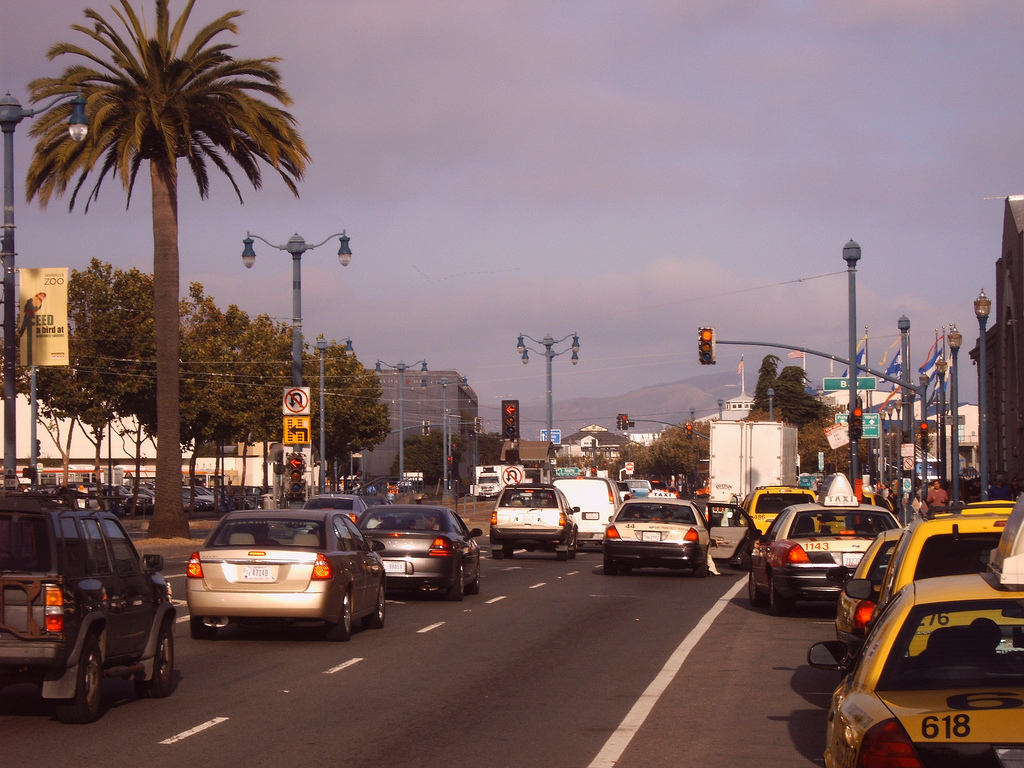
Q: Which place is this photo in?
A: It is at the road.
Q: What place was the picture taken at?
A: It was taken at the road.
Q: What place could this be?
A: It is a road.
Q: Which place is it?
A: It is a road.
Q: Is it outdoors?
A: Yes, it is outdoors.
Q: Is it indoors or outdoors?
A: It is outdoors.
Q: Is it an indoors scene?
A: No, it is outdoors.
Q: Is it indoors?
A: No, it is outdoors.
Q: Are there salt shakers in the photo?
A: No, there are no salt shakers.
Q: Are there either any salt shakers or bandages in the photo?
A: No, there are no salt shakers or bandages.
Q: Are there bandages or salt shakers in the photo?
A: No, there are no salt shakers or bandages.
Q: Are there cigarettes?
A: No, there are no cigarettes.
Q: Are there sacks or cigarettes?
A: No, there are no cigarettes or sacks.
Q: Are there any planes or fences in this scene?
A: No, there are no fences or planes.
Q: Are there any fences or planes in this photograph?
A: No, there are no fences or planes.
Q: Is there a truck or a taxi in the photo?
A: Yes, there is a taxi.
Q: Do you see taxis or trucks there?
A: Yes, there is a taxi.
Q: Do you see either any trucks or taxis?
A: Yes, there is a taxi.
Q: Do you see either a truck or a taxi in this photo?
A: Yes, there is a taxi.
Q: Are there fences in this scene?
A: No, there are no fences.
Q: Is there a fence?
A: No, there are no fences.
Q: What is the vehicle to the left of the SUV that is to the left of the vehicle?
A: The vehicle is a car.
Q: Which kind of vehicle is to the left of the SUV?
A: The vehicle is a car.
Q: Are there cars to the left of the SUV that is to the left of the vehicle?
A: Yes, there is a car to the left of the SUV.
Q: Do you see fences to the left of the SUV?
A: No, there is a car to the left of the SUV.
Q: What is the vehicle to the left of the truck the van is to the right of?
A: The vehicle is a car.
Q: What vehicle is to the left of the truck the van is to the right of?
A: The vehicle is a car.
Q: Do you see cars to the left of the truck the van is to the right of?
A: Yes, there is a car to the left of the truck.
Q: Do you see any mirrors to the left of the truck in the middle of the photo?
A: No, there is a car to the left of the truck.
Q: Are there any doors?
A: Yes, there is a door.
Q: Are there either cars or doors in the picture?
A: Yes, there is a door.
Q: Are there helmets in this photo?
A: No, there are no helmets.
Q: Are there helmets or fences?
A: No, there are no helmets or fences.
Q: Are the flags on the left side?
A: No, the flags are on the right of the image.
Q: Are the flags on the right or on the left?
A: The flags are on the right of the image.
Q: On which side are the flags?
A: The flags are on the right of the image.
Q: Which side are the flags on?
A: The flags are on the right of the image.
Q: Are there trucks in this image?
A: Yes, there is a truck.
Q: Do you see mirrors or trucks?
A: Yes, there is a truck.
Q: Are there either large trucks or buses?
A: Yes, there is a large truck.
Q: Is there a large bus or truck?
A: Yes, there is a large truck.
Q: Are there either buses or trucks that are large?
A: Yes, the truck is large.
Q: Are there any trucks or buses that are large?
A: Yes, the truck is large.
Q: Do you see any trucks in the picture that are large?
A: Yes, there is a large truck.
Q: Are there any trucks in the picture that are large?
A: Yes, there is a truck that is large.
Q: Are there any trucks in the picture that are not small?
A: Yes, there is a large truck.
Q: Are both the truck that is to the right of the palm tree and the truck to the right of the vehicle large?
A: Yes, both the truck and the truck are large.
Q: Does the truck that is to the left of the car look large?
A: Yes, the truck is large.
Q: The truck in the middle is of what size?
A: The truck is large.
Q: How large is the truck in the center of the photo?
A: The truck is large.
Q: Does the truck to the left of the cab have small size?
A: No, the truck is large.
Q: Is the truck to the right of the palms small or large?
A: The truck is large.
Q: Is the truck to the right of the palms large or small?
A: The truck is large.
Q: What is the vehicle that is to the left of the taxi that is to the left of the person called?
A: The vehicle is a truck.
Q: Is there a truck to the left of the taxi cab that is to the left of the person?
A: Yes, there is a truck to the left of the taxi.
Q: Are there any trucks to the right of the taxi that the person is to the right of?
A: No, the truck is to the left of the taxi.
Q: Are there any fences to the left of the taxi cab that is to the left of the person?
A: No, there is a truck to the left of the taxi.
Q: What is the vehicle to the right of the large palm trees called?
A: The vehicle is a truck.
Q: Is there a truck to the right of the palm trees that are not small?
A: Yes, there is a truck to the right of the palms.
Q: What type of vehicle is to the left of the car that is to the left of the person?
A: The vehicle is a truck.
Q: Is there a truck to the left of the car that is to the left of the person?
A: Yes, there is a truck to the left of the car.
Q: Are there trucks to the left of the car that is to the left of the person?
A: Yes, there is a truck to the left of the car.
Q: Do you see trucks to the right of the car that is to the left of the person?
A: No, the truck is to the left of the car.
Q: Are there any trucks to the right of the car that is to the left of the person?
A: No, the truck is to the left of the car.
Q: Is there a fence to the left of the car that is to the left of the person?
A: No, there is a truck to the left of the car.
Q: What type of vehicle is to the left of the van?
A: The vehicle is a truck.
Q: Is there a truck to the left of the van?
A: Yes, there is a truck to the left of the van.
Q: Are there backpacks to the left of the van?
A: No, there is a truck to the left of the van.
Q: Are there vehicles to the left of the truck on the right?
A: Yes, there are vehicles to the left of the truck.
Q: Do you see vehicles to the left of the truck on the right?
A: Yes, there are vehicles to the left of the truck.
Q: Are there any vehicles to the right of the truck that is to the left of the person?
A: No, the vehicles are to the left of the truck.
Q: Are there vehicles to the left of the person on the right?
A: Yes, there are vehicles to the left of the person.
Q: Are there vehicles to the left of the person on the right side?
A: Yes, there are vehicles to the left of the person.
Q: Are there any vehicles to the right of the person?
A: No, the vehicles are to the left of the person.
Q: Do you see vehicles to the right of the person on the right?
A: No, the vehicles are to the left of the person.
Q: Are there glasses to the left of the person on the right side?
A: No, there are vehicles to the left of the person.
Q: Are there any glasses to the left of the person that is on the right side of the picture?
A: No, there are vehicles to the left of the person.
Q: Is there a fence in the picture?
A: No, there are no fences.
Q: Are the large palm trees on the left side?
A: Yes, the palm trees are on the left of the image.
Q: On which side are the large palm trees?
A: The palm trees are on the left of the image.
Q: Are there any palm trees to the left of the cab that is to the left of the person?
A: Yes, there are palm trees to the left of the cab.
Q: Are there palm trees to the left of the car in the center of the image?
A: Yes, there are palm trees to the left of the car.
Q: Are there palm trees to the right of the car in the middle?
A: No, the palm trees are to the left of the car.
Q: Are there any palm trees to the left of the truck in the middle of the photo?
A: Yes, there are palm trees to the left of the truck.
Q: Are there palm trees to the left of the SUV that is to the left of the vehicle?
A: Yes, there are palm trees to the left of the SUV.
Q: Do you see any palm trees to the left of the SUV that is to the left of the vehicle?
A: Yes, there are palm trees to the left of the SUV.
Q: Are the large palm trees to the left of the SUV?
A: Yes, the palms are to the left of the SUV.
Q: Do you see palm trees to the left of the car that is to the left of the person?
A: Yes, there are palm trees to the left of the car.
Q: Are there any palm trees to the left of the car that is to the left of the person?
A: Yes, there are palm trees to the left of the car.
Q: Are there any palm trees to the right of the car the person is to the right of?
A: No, the palm trees are to the left of the car.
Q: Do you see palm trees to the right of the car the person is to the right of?
A: No, the palm trees are to the left of the car.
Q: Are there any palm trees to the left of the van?
A: Yes, there are palm trees to the left of the van.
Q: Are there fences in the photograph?
A: No, there are no fences.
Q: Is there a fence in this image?
A: No, there are no fences.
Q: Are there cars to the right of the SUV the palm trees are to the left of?
A: Yes, there is a car to the right of the SUV.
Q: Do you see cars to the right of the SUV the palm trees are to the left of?
A: Yes, there is a car to the right of the SUV.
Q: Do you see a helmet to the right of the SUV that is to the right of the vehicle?
A: No, there is a car to the right of the SUV.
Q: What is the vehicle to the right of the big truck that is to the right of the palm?
A: The vehicle is a car.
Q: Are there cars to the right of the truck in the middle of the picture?
A: Yes, there is a car to the right of the truck.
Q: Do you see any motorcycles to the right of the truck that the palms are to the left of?
A: No, there is a car to the right of the truck.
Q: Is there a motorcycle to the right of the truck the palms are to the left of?
A: No, there is a car to the right of the truck.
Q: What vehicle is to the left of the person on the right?
A: The vehicle is a car.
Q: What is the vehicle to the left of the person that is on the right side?
A: The vehicle is a car.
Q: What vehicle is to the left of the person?
A: The vehicle is a car.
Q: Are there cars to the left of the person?
A: Yes, there is a car to the left of the person.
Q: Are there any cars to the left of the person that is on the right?
A: Yes, there is a car to the left of the person.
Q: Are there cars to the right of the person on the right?
A: No, the car is to the left of the person.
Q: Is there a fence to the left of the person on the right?
A: No, there is a car to the left of the person.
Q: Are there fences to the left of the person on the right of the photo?
A: No, there is a car to the left of the person.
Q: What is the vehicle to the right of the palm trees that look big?
A: The vehicle is a car.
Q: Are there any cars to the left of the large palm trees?
A: No, the car is to the right of the palm trees.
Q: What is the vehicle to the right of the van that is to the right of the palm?
A: The vehicle is a car.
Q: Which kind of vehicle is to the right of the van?
A: The vehicle is a car.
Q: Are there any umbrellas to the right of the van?
A: No, there is a car to the right of the van.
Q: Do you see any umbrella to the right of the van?
A: No, there is a car to the right of the van.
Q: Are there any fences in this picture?
A: No, there are no fences.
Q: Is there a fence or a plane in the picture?
A: No, there are no fences or airplanes.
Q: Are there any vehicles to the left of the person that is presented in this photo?
A: Yes, there is a vehicle to the left of the person.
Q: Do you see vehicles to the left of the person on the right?
A: Yes, there is a vehicle to the left of the person.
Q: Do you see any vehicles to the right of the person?
A: No, the vehicle is to the left of the person.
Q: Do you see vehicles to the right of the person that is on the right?
A: No, the vehicle is to the left of the person.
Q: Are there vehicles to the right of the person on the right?
A: No, the vehicle is to the left of the person.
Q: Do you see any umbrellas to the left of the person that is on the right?
A: No, there is a vehicle to the left of the person.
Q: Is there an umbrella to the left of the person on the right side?
A: No, there is a vehicle to the left of the person.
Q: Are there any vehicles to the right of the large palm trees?
A: Yes, there is a vehicle to the right of the palms.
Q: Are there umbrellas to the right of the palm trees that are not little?
A: No, there is a vehicle to the right of the palms.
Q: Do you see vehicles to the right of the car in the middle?
A: Yes, there is a vehicle to the right of the car.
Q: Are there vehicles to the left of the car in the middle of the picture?
A: No, the vehicle is to the right of the car.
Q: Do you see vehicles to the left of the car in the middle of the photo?
A: No, the vehicle is to the right of the car.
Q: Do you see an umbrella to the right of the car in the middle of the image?
A: No, there is a vehicle to the right of the car.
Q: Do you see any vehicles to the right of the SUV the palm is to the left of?
A: Yes, there is a vehicle to the right of the SUV.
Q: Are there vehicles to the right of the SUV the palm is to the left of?
A: Yes, there is a vehicle to the right of the SUV.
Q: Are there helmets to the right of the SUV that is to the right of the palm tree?
A: No, there is a vehicle to the right of the SUV.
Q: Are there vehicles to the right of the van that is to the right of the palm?
A: Yes, there is a vehicle to the right of the van.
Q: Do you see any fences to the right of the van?
A: No, there is a vehicle to the right of the van.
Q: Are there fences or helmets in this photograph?
A: No, there are no fences or helmets.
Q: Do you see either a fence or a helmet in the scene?
A: No, there are no fences or helmets.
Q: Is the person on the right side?
A: Yes, the person is on the right of the image.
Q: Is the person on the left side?
A: No, the person is on the right of the image.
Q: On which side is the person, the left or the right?
A: The person is on the right of the image.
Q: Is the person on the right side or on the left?
A: The person is on the right of the image.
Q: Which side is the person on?
A: The person is on the right of the image.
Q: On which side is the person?
A: The person is on the right of the image.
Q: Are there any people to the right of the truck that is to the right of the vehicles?
A: Yes, there is a person to the right of the truck.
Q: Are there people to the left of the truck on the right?
A: No, the person is to the right of the truck.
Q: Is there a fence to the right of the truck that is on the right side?
A: No, there is a person to the right of the truck.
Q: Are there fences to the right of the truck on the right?
A: No, there is a person to the right of the truck.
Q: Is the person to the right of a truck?
A: Yes, the person is to the right of a truck.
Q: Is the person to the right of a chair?
A: No, the person is to the right of a truck.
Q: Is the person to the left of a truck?
A: No, the person is to the right of a truck.